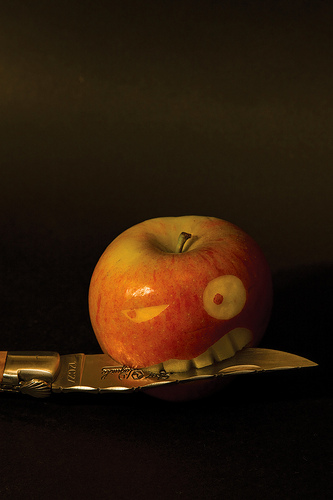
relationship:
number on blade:
[66, 361, 76, 384] [6, 349, 318, 386]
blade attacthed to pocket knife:
[44, 339, 321, 403] [1, 343, 318, 396]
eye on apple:
[196, 271, 249, 322] [77, 209, 282, 390]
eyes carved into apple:
[106, 273, 241, 326] [107, 218, 248, 367]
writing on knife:
[66, 361, 77, 385] [0, 345, 317, 391]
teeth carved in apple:
[123, 328, 264, 375] [86, 213, 273, 372]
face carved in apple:
[105, 266, 264, 377] [90, 201, 264, 369]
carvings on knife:
[100, 363, 175, 386] [0, 345, 317, 391]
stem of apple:
[174, 230, 190, 254] [88, 215, 273, 400]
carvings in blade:
[100, 363, 175, 386] [83, 345, 318, 394]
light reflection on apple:
[127, 285, 157, 298] [88, 215, 273, 400]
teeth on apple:
[123, 328, 264, 375] [86, 213, 273, 372]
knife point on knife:
[286, 349, 319, 369] [5, 326, 322, 391]